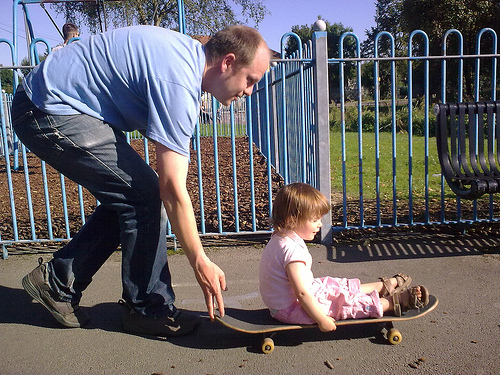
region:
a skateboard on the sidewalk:
[209, 286, 454, 354]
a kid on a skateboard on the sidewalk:
[201, 182, 448, 353]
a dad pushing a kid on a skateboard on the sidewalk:
[17, 28, 457, 357]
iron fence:
[324, 25, 487, 237]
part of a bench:
[436, 83, 490, 206]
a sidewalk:
[10, 242, 498, 356]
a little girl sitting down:
[248, 180, 425, 322]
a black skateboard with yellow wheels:
[209, 293, 439, 353]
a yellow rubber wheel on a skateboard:
[262, 338, 273, 352]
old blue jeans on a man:
[8, 85, 173, 310]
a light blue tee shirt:
[20, 26, 207, 153]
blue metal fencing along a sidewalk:
[0, 28, 496, 257]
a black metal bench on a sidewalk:
[434, 100, 499, 197]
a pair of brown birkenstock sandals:
[377, 272, 427, 314]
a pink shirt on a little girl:
[259, 228, 313, 306]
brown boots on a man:
[19, 262, 194, 337]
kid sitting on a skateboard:
[224, 168, 451, 350]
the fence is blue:
[324, 15, 484, 236]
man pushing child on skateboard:
[24, 19, 437, 359]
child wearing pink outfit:
[265, 189, 420, 322]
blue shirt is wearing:
[40, 19, 202, 144]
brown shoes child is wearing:
[382, 277, 428, 312]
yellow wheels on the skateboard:
[257, 325, 405, 352]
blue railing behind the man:
[3, 35, 485, 243]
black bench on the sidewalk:
[438, 99, 499, 200]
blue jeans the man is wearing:
[16, 105, 175, 307]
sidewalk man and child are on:
[3, 252, 494, 372]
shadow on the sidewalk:
[330, 218, 495, 255]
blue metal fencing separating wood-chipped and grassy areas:
[1, 20, 494, 251]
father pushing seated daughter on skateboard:
[12, 23, 440, 354]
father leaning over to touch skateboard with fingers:
[12, 22, 271, 352]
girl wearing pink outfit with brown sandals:
[257, 180, 431, 331]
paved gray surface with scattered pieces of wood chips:
[5, 226, 492, 369]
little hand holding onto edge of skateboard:
[240, 310, 420, 334]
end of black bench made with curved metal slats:
[427, 93, 496, 205]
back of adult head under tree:
[55, 5, 81, 44]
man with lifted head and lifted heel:
[9, 22, 271, 341]